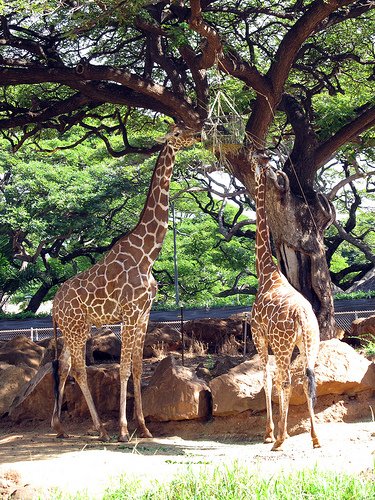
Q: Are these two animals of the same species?
A: Yes, all the animals are giraffes.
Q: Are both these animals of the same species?
A: Yes, all the animals are giraffes.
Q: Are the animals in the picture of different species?
A: No, all the animals are giraffes.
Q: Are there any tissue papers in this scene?
A: No, there are no tissue papers.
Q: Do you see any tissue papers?
A: No, there are no tissue papers.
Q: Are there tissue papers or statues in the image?
A: No, there are no tissue papers or statues.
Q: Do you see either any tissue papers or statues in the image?
A: No, there are no tissue papers or statues.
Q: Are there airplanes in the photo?
A: No, there are no airplanes.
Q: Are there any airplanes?
A: No, there are no airplanes.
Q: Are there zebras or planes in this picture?
A: No, there are no planes or zebras.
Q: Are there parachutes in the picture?
A: No, there are no parachutes.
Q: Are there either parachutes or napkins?
A: No, there are no parachutes or napkins.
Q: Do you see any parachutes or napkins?
A: No, there are no parachutes or napkins.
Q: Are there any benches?
A: No, there are no benches.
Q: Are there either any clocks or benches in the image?
A: No, there are no benches or clocks.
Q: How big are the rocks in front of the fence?
A: The rocks are large.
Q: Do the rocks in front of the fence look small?
A: No, the rocks are large.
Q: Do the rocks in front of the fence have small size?
A: No, the rocks are large.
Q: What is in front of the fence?
A: The rocks are in front of the fence.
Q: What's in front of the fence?
A: The rocks are in front of the fence.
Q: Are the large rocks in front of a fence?
A: Yes, the rocks are in front of a fence.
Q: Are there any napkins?
A: No, there are no napkins.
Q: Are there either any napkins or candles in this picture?
A: No, there are no napkins or candles.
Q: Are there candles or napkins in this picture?
A: No, there are no napkins or candles.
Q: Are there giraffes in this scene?
A: Yes, there is a giraffe.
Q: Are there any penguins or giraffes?
A: Yes, there is a giraffe.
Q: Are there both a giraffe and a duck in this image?
A: No, there is a giraffe but no ducks.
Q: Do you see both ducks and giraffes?
A: No, there is a giraffe but no ducks.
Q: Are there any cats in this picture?
A: No, there are no cats.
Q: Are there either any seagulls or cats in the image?
A: No, there are no cats or seagulls.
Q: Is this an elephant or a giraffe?
A: This is a giraffe.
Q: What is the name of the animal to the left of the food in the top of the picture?
A: The animal is a giraffe.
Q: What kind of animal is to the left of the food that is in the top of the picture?
A: The animal is a giraffe.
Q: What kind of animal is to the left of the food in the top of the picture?
A: The animal is a giraffe.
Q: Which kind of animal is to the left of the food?
A: The animal is a giraffe.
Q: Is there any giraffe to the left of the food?
A: Yes, there is a giraffe to the left of the food.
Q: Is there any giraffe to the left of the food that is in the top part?
A: Yes, there is a giraffe to the left of the food.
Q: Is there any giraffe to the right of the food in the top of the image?
A: No, the giraffe is to the left of the food.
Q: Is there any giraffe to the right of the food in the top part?
A: No, the giraffe is to the left of the food.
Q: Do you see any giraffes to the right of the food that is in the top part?
A: No, the giraffe is to the left of the food.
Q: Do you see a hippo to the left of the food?
A: No, there is a giraffe to the left of the food.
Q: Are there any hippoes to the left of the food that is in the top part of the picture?
A: No, there is a giraffe to the left of the food.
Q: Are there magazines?
A: No, there are no magazines.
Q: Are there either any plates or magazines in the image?
A: No, there are no magazines or plates.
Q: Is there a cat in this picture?
A: No, there are no cats.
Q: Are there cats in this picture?
A: No, there are no cats.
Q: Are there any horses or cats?
A: No, there are no cats or horses.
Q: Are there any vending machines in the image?
A: No, there are no vending machines.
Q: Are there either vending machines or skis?
A: No, there are no vending machines or skis.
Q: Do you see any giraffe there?
A: Yes, there is a giraffe.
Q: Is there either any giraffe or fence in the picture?
A: Yes, there is a giraffe.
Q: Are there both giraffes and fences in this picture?
A: Yes, there are both a giraffe and a fence.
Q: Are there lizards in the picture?
A: No, there are no lizards.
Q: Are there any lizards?
A: No, there are no lizards.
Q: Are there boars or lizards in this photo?
A: No, there are no lizards or boars.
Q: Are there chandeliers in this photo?
A: No, there are no chandeliers.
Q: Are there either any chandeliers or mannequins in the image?
A: No, there are no chandeliers or mannequins.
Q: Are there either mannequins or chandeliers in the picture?
A: No, there are no chandeliers or mannequins.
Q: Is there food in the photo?
A: Yes, there is food.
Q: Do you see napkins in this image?
A: No, there are no napkins.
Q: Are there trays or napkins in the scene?
A: No, there are no napkins or trays.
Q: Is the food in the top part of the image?
A: Yes, the food is in the top of the image.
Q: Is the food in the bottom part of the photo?
A: No, the food is in the top of the image.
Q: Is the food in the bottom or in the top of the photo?
A: The food is in the top of the image.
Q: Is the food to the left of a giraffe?
A: No, the food is to the right of a giraffe.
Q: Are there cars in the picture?
A: No, there are no cars.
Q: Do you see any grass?
A: Yes, there is grass.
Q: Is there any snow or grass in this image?
A: Yes, there is grass.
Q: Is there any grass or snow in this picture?
A: Yes, there is grass.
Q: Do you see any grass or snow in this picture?
A: Yes, there is grass.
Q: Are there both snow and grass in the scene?
A: No, there is grass but no snow.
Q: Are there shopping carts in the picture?
A: No, there are no shopping carts.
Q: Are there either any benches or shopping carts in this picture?
A: No, there are no shopping carts or benches.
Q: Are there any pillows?
A: No, there are no pillows.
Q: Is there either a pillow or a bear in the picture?
A: No, there are no pillows or bears.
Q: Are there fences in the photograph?
A: Yes, there is a fence.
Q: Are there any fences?
A: Yes, there is a fence.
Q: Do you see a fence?
A: Yes, there is a fence.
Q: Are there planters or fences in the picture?
A: Yes, there is a fence.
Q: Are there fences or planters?
A: Yes, there is a fence.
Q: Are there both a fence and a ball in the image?
A: No, there is a fence but no balls.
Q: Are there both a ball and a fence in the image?
A: No, there is a fence but no balls.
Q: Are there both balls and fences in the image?
A: No, there is a fence but no balls.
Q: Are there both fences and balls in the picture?
A: No, there is a fence but no balls.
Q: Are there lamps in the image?
A: No, there are no lamps.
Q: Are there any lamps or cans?
A: No, there are no lamps or cans.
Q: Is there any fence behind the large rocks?
A: Yes, there is a fence behind the rocks.